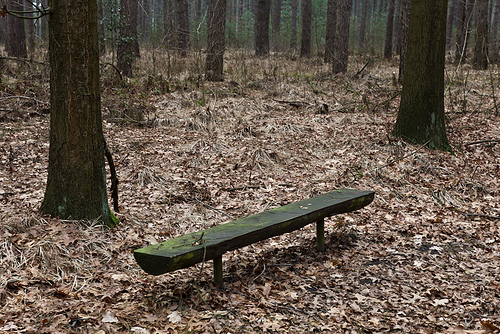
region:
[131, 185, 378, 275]
Wooden bench in forest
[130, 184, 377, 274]
Bench seat made of log sawed in half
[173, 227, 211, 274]
Twig on bench seat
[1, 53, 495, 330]
Leaf strewn forest ground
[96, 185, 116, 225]
Moss growing on base of tree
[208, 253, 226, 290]
Wooden support pole for bench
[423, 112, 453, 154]
Moss growing on base of tree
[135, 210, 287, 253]
Green moss stains on bench seat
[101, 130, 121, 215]
Fallen branch leaning against tree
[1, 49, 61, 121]
Brush pile in forest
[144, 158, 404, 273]
this is a bench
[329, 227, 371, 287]
these are leaves on the ground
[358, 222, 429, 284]
these are leaves on the ground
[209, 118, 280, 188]
these are leaves on the ground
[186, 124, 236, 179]
these are leaves on the ground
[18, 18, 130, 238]
this is a tree trunk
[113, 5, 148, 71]
this is a tree trunk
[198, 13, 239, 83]
this is a tree trunk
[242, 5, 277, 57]
this is a tree trunk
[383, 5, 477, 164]
this is a tree trunk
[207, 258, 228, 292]
this is a chair stand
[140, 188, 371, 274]
this is a sitting foam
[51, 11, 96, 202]
this is a stem of a tree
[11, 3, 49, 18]
this is a branch of a tree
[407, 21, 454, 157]
this is a stem of a tree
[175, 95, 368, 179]
this is dry grass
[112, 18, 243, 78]
these are tree branches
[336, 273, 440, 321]
these are dry leaves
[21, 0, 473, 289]
this is a forest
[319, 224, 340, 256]
this is a sitting bench stand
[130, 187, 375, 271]
The wooden bench.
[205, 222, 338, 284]
The legs of the wooden bench.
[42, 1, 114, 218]
The tree on the left.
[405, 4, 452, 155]
The tree on the right.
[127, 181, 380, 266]
The sitting area of the bench.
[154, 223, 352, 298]
The leaves under the bench.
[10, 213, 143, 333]
The leaves to the left of the bench.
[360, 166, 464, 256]
The leaves to the right of the bench.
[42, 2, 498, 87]
The trees in the background.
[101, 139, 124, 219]
The branch against the tree on the left.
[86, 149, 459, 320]
a small bench in the park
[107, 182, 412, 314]
a small bench in the forest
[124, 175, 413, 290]
a table in the park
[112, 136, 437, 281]
a table in the forest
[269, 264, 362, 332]
leaves on the floor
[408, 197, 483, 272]
leaves on the ground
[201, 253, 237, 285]
stand of the bench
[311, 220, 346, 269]
right stand of the bench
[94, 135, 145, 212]
a part of the tree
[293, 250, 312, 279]
shadow on the ground